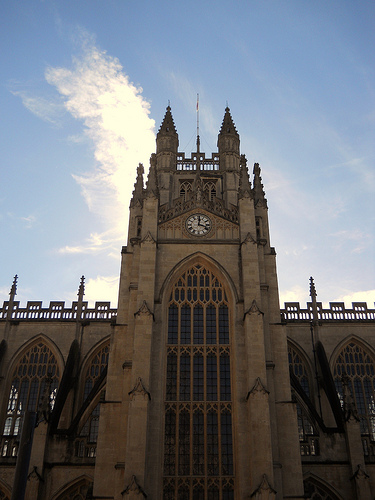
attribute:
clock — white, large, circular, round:
[185, 209, 216, 243]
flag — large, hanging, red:
[190, 90, 209, 112]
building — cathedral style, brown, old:
[88, 88, 313, 499]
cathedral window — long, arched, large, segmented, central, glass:
[156, 248, 239, 497]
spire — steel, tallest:
[193, 110, 209, 150]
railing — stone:
[4, 295, 120, 323]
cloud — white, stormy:
[32, 40, 152, 148]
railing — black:
[47, 340, 77, 454]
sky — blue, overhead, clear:
[0, 1, 375, 304]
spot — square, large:
[246, 262, 261, 285]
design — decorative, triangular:
[8, 96, 374, 493]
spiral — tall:
[214, 98, 250, 140]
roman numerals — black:
[205, 222, 213, 227]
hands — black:
[197, 221, 205, 222]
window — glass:
[177, 177, 193, 199]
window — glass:
[201, 179, 221, 202]